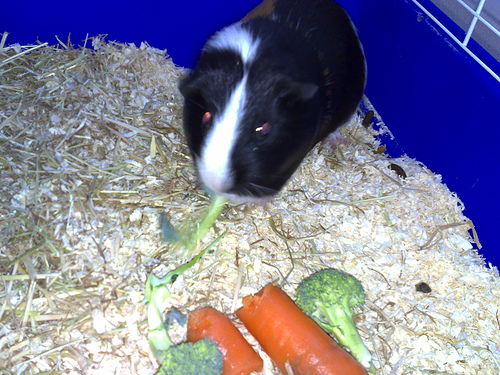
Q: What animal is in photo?
A: Guinea pig.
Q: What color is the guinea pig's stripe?
A: White.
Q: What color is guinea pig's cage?
A: Blue.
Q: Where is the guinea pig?
A: In it's cage.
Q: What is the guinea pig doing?
A: Eating.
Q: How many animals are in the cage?
A: 1.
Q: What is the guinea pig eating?
A: Carrots and broccoli.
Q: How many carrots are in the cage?
A: 2.